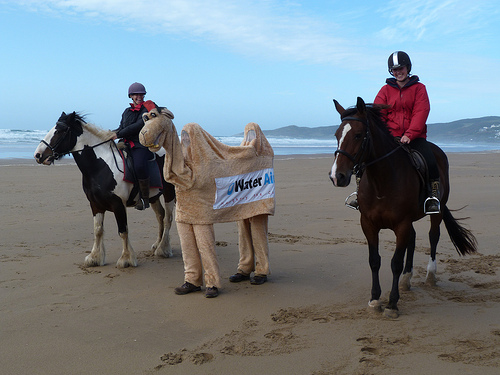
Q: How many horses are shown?
A: 2.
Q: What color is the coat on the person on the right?
A: Red.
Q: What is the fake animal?
A: Camel.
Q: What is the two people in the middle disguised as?
A: A camel.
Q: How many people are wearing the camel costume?
A: Two.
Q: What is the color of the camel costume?
A: Brown.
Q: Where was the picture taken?
A: On the beach.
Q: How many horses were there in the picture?
A: Two.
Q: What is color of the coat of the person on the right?
A: Red.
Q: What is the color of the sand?
A: Brown.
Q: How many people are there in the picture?
A: Four.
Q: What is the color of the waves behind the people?
A: White.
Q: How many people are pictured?
A: 4.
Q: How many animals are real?
A: 2.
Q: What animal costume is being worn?
A: A camel.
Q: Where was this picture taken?
A: Beach.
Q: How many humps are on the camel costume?
A: 2.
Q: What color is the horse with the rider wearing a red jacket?
A: Brown.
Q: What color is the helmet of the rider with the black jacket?
A: Grey.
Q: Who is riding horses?
A: Two women.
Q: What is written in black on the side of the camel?
A: Water.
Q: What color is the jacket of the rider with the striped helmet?
A: Red.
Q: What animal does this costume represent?
A: Camel.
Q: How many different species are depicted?
A: Two.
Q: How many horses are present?
A: Two.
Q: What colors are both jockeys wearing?
A: Black and red.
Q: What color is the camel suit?
A: Tan.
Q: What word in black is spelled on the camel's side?
A: Water.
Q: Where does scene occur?
A: On beach.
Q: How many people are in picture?
A: 4.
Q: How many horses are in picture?
A: 2.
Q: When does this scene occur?
A: Daytime.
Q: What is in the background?
A: Ocean and hills.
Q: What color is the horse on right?
A: Brown.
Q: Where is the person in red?
A: On the right.